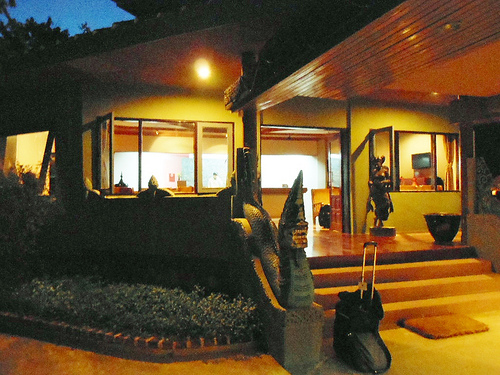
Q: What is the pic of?
A: A house.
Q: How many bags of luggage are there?
A: 1.